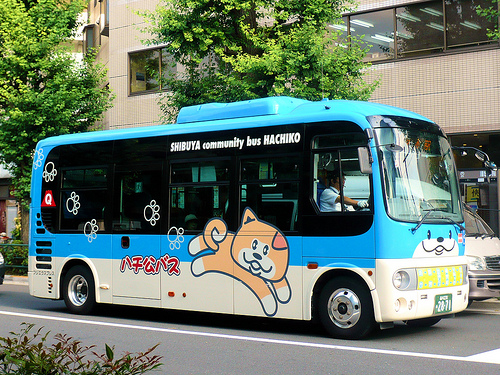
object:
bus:
[22, 96, 496, 345]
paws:
[261, 299, 276, 315]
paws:
[274, 289, 293, 305]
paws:
[189, 257, 204, 277]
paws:
[186, 236, 201, 257]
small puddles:
[114, 178, 136, 253]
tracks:
[138, 188, 185, 241]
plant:
[130, 0, 385, 143]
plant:
[1, 318, 166, 373]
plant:
[1, 1, 117, 275]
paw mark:
[39, 161, 57, 184]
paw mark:
[66, 192, 83, 214]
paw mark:
[84, 217, 102, 243]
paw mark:
[143, 199, 163, 226]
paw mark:
[166, 224, 187, 251]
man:
[318, 172, 370, 215]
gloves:
[353, 199, 372, 210]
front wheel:
[316, 271, 375, 342]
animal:
[185, 207, 295, 317]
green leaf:
[24, 97, 32, 103]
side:
[31, 117, 375, 314]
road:
[2, 285, 500, 374]